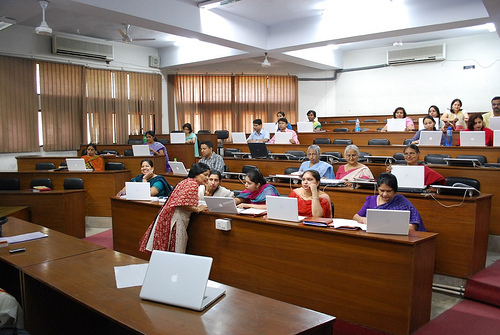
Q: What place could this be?
A: It is a classroom.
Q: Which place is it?
A: It is a classroom.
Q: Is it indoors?
A: Yes, it is indoors.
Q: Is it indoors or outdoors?
A: It is indoors.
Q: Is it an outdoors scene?
A: No, it is indoors.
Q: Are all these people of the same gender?
A: Yes, all the people are female.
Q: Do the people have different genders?
A: No, all the people are female.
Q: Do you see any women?
A: Yes, there is a woman.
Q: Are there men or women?
A: Yes, there is a woman.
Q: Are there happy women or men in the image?
A: Yes, there is a happy woman.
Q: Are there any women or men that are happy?
A: Yes, the woman is happy.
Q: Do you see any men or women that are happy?
A: Yes, the woman is happy.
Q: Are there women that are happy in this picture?
A: Yes, there is a happy woman.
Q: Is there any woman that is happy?
A: Yes, there is a woman that is happy.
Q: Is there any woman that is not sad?
A: Yes, there is a happy woman.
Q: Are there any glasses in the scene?
A: No, there are no glasses.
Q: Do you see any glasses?
A: No, there are no glasses.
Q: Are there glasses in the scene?
A: No, there are no glasses.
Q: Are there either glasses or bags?
A: No, there are no glasses or bags.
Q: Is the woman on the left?
A: Yes, the woman is on the left of the image.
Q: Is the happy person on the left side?
A: Yes, the woman is on the left of the image.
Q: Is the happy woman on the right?
A: No, the woman is on the left of the image.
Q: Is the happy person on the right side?
A: No, the woman is on the left of the image.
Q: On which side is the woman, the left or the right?
A: The woman is on the left of the image.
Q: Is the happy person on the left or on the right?
A: The woman is on the left of the image.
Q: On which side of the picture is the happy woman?
A: The woman is on the left of the image.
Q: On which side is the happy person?
A: The woman is on the left of the image.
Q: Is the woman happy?
A: Yes, the woman is happy.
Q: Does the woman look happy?
A: Yes, the woman is happy.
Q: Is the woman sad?
A: No, the woman is happy.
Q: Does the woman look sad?
A: No, the woman is happy.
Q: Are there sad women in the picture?
A: No, there is a woman but she is happy.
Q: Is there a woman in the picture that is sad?
A: No, there is a woman but she is happy.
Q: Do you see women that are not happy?
A: No, there is a woman but she is happy.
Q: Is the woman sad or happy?
A: The woman is happy.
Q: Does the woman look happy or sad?
A: The woman is happy.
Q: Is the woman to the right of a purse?
A: No, the woman is to the right of the chair.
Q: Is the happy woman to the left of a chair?
A: No, the woman is to the right of a chair.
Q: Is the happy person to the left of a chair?
A: No, the woman is to the right of a chair.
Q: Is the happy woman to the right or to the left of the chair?
A: The woman is to the right of the chair.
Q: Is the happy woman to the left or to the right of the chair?
A: The woman is to the right of the chair.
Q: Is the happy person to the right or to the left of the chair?
A: The woman is to the right of the chair.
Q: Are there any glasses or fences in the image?
A: No, there are no fences or glasses.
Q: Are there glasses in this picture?
A: No, there are no glasses.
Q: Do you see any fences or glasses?
A: No, there are no glasses or fences.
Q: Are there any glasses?
A: No, there are no glasses.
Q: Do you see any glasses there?
A: No, there are no glasses.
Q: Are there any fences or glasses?
A: No, there are no glasses or fences.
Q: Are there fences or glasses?
A: No, there are no glasses or fences.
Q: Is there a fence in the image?
A: No, there are no fences.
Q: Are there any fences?
A: No, there are no fences.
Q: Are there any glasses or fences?
A: No, there are no fences or glasses.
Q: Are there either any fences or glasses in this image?
A: No, there are no fences or glasses.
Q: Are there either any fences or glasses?
A: No, there are no fences or glasses.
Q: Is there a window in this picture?
A: Yes, there is a window.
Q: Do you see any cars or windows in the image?
A: Yes, there is a window.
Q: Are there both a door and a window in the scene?
A: No, there is a window but no doors.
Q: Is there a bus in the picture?
A: No, there are no buses.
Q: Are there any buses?
A: No, there are no buses.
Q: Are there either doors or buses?
A: No, there are no buses or doors.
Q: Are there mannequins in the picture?
A: No, there are no mannequins.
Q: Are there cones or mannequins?
A: No, there are no mannequins or cones.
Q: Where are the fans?
A: The fans are in the classroom.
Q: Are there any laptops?
A: Yes, there is a laptop.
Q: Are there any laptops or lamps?
A: Yes, there is a laptop.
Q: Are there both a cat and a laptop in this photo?
A: No, there is a laptop but no cats.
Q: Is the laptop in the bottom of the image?
A: Yes, the laptop is in the bottom of the image.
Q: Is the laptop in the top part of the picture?
A: No, the laptop is in the bottom of the image.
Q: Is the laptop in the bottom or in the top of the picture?
A: The laptop is in the bottom of the image.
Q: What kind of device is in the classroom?
A: The device is a laptop.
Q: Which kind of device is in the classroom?
A: The device is a laptop.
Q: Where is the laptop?
A: The laptop is in the classroom.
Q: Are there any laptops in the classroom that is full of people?
A: Yes, there is a laptop in the classroom.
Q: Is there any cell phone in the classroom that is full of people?
A: No, there is a laptop in the classroom.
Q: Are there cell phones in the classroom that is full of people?
A: No, there is a laptop in the classroom.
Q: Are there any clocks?
A: No, there are no clocks.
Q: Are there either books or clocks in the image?
A: No, there are no clocks or books.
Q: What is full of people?
A: The classroom is full of people.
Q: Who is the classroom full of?
A: The classroom is full of people.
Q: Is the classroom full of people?
A: Yes, the classroom is full of people.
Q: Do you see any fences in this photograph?
A: No, there are no fences.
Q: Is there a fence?
A: No, there are no fences.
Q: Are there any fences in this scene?
A: No, there are no fences.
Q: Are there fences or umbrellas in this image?
A: No, there are no fences or umbrellas.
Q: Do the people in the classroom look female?
A: Yes, the people are female.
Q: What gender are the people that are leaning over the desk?
A: The people are female.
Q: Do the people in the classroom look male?
A: No, the people are female.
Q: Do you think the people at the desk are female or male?
A: The people are female.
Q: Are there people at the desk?
A: Yes, there are people at the desk.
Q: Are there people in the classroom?
A: Yes, there are people in the classroom.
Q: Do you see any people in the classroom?
A: Yes, there are people in the classroom.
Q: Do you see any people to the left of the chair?
A: No, the people are to the right of the chair.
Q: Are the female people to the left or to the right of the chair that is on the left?
A: The people are to the right of the chair.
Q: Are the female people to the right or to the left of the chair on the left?
A: The people are to the right of the chair.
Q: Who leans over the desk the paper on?
A: The people lean over the desk.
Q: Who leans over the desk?
A: The people lean over the desk.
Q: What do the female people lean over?
A: The people lean over the desk.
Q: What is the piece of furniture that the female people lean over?
A: The piece of furniture is a desk.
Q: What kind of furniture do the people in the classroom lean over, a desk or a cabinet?
A: The people lean over a desk.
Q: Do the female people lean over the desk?
A: Yes, the people lean over the desk.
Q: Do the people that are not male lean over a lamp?
A: No, the people lean over the desk.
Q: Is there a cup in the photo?
A: No, there are no cups.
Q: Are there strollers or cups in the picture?
A: No, there are no cups or strollers.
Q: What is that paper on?
A: The paper is on the desk.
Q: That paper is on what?
A: The paper is on the desk.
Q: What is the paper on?
A: The paper is on the desk.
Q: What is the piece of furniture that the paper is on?
A: The piece of furniture is a desk.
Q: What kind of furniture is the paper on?
A: The paper is on the desk.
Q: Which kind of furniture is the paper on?
A: The paper is on the desk.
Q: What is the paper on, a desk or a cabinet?
A: The paper is on a desk.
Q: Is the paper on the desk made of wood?
A: Yes, the paper is on the desk.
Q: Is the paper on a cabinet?
A: No, the paper is on the desk.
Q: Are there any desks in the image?
A: Yes, there is a desk.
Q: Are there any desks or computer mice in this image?
A: Yes, there is a desk.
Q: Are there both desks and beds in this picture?
A: No, there is a desk but no beds.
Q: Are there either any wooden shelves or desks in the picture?
A: Yes, there is a wood desk.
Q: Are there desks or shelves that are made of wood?
A: Yes, the desk is made of wood.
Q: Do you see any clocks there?
A: No, there are no clocks.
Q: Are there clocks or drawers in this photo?
A: No, there are no clocks or drawers.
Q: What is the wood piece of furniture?
A: The piece of furniture is a desk.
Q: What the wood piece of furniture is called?
A: The piece of furniture is a desk.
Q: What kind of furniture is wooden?
A: The furniture is a desk.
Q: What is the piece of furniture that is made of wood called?
A: The piece of furniture is a desk.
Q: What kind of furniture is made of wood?
A: The furniture is a desk.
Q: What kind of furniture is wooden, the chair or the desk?
A: The desk is wooden.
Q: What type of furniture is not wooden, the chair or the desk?
A: The chair is not wooden.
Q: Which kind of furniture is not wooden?
A: The furniture is a chair.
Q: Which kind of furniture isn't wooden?
A: The furniture is a chair.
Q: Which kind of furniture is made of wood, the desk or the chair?
A: The desk is made of wood.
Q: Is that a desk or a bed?
A: That is a desk.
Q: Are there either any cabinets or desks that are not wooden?
A: No, there is a desk but it is wooden.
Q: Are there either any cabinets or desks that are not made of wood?
A: No, there is a desk but it is made of wood.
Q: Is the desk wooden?
A: Yes, the desk is wooden.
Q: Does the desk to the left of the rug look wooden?
A: Yes, the desk is wooden.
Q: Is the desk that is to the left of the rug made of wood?
A: Yes, the desk is made of wood.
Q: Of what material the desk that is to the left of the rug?
A: The desk is made of wood.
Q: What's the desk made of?
A: The desk is made of wood.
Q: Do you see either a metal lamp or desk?
A: No, there is a desk but it is wooden.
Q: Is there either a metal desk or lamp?
A: No, there is a desk but it is wooden.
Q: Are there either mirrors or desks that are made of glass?
A: No, there is a desk but it is made of wood.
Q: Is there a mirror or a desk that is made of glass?
A: No, there is a desk but it is made of wood.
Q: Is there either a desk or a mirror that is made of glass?
A: No, there is a desk but it is made of wood.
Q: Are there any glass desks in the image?
A: No, there is a desk but it is made of wood.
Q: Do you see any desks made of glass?
A: No, there is a desk but it is made of wood.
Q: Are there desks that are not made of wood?
A: No, there is a desk but it is made of wood.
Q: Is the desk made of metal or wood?
A: The desk is made of wood.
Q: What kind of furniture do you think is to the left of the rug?
A: The piece of furniture is a desk.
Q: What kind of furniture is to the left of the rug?
A: The piece of furniture is a desk.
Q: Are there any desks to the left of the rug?
A: Yes, there is a desk to the left of the rug.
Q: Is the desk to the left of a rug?
A: Yes, the desk is to the left of a rug.